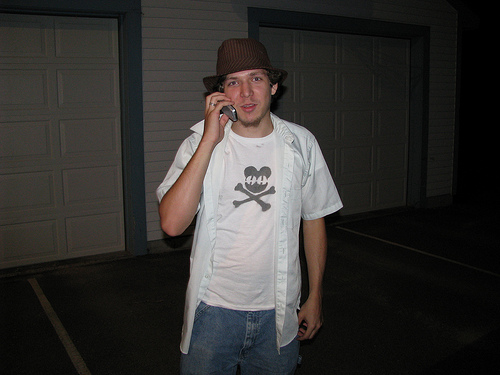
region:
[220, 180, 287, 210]
silver skull and cross bone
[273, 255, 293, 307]
white seam on shirt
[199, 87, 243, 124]
silver and black phone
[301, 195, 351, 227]
short sleeve on white shirt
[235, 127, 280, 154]
collar on white shirt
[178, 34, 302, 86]
brown hat on head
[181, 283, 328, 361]
pair of blue jeans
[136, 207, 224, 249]
man's white elbow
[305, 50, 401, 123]
large white door on garage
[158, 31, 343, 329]
man standing in front of garage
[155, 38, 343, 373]
Young adult male talking on cellphone.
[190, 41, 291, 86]
boy has brown hat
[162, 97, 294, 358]
boy has white shirt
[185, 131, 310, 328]
white and grey shirt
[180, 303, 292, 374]
boy has blue jeans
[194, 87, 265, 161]
boy is holding phone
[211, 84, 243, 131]
boy holds grey phone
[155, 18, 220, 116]
white wall behind boy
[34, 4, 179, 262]
green frame around door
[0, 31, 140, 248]
white garage doors behind boy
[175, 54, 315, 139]
boy has dark hair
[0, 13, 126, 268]
A white garage door.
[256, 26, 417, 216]
A closed garage door.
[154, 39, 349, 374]
A young man holding a phone.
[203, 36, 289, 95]
A striped hat.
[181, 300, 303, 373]
A pair of blue jeans.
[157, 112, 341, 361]
A white button up shirt.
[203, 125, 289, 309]
A white tshirt with black art.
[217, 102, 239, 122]
A silver color cell phone.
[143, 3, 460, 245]
A white wall.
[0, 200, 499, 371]
An area of paved parkinglot.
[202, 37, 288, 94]
the hat on the man's head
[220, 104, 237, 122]
the phone the man is holding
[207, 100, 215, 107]
the ring on the man's finger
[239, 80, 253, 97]
the nose on the man's face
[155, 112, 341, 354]
the man's button up shirt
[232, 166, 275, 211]
the design on the man's shirt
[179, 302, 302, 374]
the denim jeans on the man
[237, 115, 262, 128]
the chin hair on the man's face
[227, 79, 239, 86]
the eye on the man's face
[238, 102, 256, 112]
the mouth on the man's face